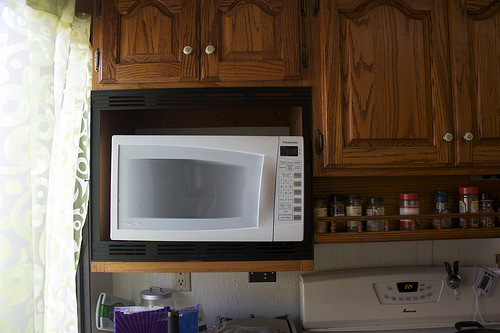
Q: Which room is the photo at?
A: It is at the kitchen.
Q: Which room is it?
A: It is a kitchen.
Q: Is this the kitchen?
A: Yes, it is the kitchen.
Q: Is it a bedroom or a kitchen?
A: It is a kitchen.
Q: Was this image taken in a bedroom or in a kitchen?
A: It was taken at a kitchen.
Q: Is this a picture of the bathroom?
A: No, the picture is showing the kitchen.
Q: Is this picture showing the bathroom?
A: No, the picture is showing the kitchen.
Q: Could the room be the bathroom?
A: No, it is the kitchen.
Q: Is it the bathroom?
A: No, it is the kitchen.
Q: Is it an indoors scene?
A: Yes, it is indoors.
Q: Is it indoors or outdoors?
A: It is indoors.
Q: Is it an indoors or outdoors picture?
A: It is indoors.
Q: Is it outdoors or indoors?
A: It is indoors.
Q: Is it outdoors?
A: No, it is indoors.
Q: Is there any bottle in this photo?
A: Yes, there is a bottle.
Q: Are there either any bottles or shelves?
A: Yes, there is a bottle.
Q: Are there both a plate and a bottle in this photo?
A: No, there is a bottle but no plates.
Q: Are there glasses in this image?
A: No, there are no glasses.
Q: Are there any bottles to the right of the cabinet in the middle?
A: Yes, there is a bottle to the right of the cabinet.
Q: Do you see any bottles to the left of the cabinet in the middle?
A: No, the bottle is to the right of the cabinet.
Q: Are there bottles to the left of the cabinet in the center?
A: No, the bottle is to the right of the cabinet.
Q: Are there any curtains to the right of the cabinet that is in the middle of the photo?
A: No, there is a bottle to the right of the cabinet.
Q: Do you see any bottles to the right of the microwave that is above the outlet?
A: Yes, there is a bottle to the right of the microwave.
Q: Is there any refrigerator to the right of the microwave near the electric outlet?
A: No, there is a bottle to the right of the microwave.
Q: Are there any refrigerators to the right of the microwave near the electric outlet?
A: No, there is a bottle to the right of the microwave.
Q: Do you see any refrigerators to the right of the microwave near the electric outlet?
A: No, there is a bottle to the right of the microwave.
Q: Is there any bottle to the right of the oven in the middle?
A: Yes, there is a bottle to the right of the oven.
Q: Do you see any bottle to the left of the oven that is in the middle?
A: No, the bottle is to the right of the oven.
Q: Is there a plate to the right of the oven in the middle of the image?
A: No, there is a bottle to the right of the oven.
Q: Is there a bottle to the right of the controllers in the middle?
A: Yes, there is a bottle to the right of the controllers.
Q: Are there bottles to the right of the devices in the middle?
A: Yes, there is a bottle to the right of the controllers.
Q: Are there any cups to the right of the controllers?
A: No, there is a bottle to the right of the controllers.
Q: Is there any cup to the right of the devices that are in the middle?
A: No, there is a bottle to the right of the controllers.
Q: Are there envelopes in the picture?
A: No, there are no envelopes.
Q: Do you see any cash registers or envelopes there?
A: No, there are no envelopes or cash registers.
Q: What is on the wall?
A: The electrical outlet is on the wall.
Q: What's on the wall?
A: The electrical outlet is on the wall.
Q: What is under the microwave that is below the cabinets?
A: The outlet is under the microwave.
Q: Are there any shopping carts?
A: No, there are no shopping carts.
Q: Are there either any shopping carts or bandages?
A: No, there are no shopping carts or bandages.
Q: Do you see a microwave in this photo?
A: Yes, there is a microwave.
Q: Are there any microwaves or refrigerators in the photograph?
A: Yes, there is a microwave.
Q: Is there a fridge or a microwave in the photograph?
A: Yes, there is a microwave.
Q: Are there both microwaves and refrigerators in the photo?
A: No, there is a microwave but no refrigerators.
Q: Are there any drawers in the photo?
A: No, there are no drawers.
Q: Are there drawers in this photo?
A: No, there are no drawers.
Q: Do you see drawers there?
A: No, there are no drawers.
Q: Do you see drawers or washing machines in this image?
A: No, there are no drawers or washing machines.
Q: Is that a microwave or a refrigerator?
A: That is a microwave.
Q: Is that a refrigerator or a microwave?
A: That is a microwave.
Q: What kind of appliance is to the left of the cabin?
A: The appliance is a microwave.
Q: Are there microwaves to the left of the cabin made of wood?
A: Yes, there is a microwave to the left of the cabin.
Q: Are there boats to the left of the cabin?
A: No, there is a microwave to the left of the cabin.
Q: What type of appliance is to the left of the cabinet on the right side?
A: The appliance is a microwave.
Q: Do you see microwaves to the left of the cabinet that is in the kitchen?
A: Yes, there is a microwave to the left of the cabinet.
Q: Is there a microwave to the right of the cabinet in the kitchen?
A: No, the microwave is to the left of the cabinet.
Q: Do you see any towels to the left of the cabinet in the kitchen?
A: No, there is a microwave to the left of the cabinet.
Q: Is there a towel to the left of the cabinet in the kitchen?
A: No, there is a microwave to the left of the cabinet.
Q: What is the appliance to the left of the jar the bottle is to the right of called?
A: The appliance is a microwave.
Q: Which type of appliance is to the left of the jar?
A: The appliance is a microwave.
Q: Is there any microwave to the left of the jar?
A: Yes, there is a microwave to the left of the jar.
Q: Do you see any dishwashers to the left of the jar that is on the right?
A: No, there is a microwave to the left of the jar.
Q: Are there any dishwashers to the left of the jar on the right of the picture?
A: No, there is a microwave to the left of the jar.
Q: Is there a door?
A: Yes, there are doors.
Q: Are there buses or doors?
A: Yes, there are doors.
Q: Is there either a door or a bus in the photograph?
A: Yes, there are doors.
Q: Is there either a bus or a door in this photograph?
A: Yes, there are doors.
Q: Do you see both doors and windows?
A: Yes, there are both doors and a window.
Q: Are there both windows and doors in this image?
A: Yes, there are both doors and a window.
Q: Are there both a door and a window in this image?
A: Yes, there are both a door and a window.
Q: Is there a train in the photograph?
A: No, there are no trains.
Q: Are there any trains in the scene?
A: No, there are no trains.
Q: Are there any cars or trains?
A: No, there are no trains or cars.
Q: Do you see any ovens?
A: Yes, there is an oven.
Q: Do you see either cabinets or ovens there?
A: Yes, there is an oven.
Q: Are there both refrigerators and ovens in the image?
A: No, there is an oven but no refrigerators.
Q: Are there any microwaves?
A: Yes, there is a microwave.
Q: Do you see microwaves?
A: Yes, there is a microwave.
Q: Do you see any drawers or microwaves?
A: Yes, there is a microwave.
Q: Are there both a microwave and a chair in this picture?
A: No, there is a microwave but no chairs.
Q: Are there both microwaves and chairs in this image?
A: No, there is a microwave but no chairs.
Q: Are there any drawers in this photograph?
A: No, there are no drawers.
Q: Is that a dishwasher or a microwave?
A: That is a microwave.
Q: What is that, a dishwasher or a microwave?
A: That is a microwave.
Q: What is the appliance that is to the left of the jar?
A: The appliance is a microwave.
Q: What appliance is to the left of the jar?
A: The appliance is a microwave.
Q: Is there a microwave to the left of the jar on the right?
A: Yes, there is a microwave to the left of the jar.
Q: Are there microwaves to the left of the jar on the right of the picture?
A: Yes, there is a microwave to the left of the jar.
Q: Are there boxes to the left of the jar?
A: No, there is a microwave to the left of the jar.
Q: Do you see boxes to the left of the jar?
A: No, there is a microwave to the left of the jar.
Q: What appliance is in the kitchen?
A: The appliance is a microwave.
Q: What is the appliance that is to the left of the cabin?
A: The appliance is a microwave.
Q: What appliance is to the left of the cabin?
A: The appliance is a microwave.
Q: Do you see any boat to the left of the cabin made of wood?
A: No, there is a microwave to the left of the cabin.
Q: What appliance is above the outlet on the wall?
A: The appliance is a microwave.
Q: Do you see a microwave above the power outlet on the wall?
A: Yes, there is a microwave above the outlet.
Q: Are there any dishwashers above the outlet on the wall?
A: No, there is a microwave above the outlet.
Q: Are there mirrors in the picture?
A: No, there are no mirrors.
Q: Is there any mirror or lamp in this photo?
A: No, there are no mirrors or lamps.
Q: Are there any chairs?
A: No, there are no chairs.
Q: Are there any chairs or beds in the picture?
A: No, there are no chairs or beds.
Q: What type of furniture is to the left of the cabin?
A: The pieces of furniture are cabinets.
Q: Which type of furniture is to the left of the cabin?
A: The pieces of furniture are cabinets.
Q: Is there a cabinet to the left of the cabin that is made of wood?
A: Yes, there are cabinets to the left of the cabin.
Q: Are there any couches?
A: No, there are no couches.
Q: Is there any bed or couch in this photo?
A: No, there are no couches or beds.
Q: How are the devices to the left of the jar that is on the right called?
A: The devices are controllers.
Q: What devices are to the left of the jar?
A: The devices are controllers.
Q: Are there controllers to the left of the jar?
A: Yes, there are controllers to the left of the jar.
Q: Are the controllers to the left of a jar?
A: Yes, the controllers are to the left of a jar.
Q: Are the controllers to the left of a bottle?
A: Yes, the controllers are to the left of a bottle.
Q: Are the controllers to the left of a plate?
A: No, the controllers are to the left of a bottle.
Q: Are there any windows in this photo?
A: Yes, there is a window.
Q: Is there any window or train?
A: Yes, there is a window.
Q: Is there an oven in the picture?
A: Yes, there is an oven.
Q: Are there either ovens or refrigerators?
A: Yes, there is an oven.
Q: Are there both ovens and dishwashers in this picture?
A: No, there is an oven but no dishwashers.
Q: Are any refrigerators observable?
A: No, there are no refrigerators.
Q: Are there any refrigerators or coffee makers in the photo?
A: No, there are no refrigerators or coffee makers.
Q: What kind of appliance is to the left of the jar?
A: The appliance is an oven.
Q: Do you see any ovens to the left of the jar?
A: Yes, there is an oven to the left of the jar.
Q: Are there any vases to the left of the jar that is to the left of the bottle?
A: No, there is an oven to the left of the jar.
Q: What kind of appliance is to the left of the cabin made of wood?
A: The appliance is an oven.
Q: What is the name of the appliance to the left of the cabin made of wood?
A: The appliance is an oven.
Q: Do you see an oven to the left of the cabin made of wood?
A: Yes, there is an oven to the left of the cabin.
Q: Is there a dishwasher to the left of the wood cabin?
A: No, there is an oven to the left of the cabin.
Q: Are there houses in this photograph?
A: No, there are no houses.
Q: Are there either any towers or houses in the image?
A: No, there are no houses or towers.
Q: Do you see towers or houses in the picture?
A: No, there are no houses or towers.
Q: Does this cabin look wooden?
A: Yes, the cabin is wooden.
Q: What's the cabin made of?
A: The cabin is made of wood.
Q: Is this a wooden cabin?
A: Yes, this is a wooden cabin.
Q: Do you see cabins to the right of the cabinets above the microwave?
A: Yes, there is a cabin to the right of the cabinets.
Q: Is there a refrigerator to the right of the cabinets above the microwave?
A: No, there is a cabin to the right of the cabinets.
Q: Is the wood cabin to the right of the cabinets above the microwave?
A: Yes, the cabin is to the right of the cabinets.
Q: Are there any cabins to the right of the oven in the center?
A: Yes, there is a cabin to the right of the oven.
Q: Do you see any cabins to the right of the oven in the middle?
A: Yes, there is a cabin to the right of the oven.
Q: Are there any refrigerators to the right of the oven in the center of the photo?
A: No, there is a cabin to the right of the oven.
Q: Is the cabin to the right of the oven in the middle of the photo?
A: Yes, the cabin is to the right of the oven.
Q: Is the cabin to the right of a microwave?
A: Yes, the cabin is to the right of a microwave.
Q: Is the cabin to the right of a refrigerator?
A: No, the cabin is to the right of a microwave.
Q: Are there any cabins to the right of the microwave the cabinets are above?
A: Yes, there is a cabin to the right of the microwave.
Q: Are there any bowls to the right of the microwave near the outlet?
A: No, there is a cabin to the right of the microwave.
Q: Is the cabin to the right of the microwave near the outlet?
A: Yes, the cabin is to the right of the microwave.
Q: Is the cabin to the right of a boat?
A: No, the cabin is to the right of the microwave.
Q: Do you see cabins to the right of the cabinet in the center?
A: Yes, there is a cabin to the right of the cabinet.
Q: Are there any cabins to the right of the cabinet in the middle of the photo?
A: Yes, there is a cabin to the right of the cabinet.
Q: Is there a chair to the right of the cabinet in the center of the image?
A: No, there is a cabin to the right of the cabinet.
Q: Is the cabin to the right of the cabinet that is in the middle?
A: Yes, the cabin is to the right of the cabinet.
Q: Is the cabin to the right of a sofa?
A: No, the cabin is to the right of the cabinet.